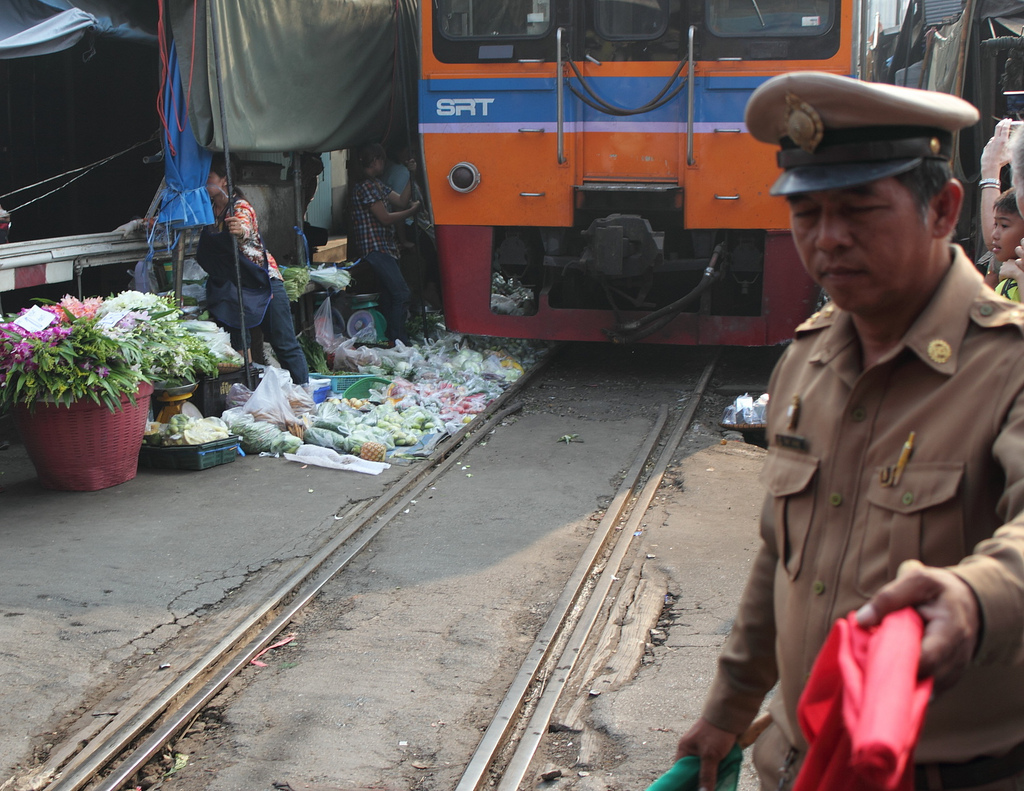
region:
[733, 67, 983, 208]
the man wears a tan hat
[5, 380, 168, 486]
the red pot holding the plant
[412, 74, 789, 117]
the blue stripe on the train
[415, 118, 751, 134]
the white stripe on the train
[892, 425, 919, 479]
the pen in the mans shirt is gold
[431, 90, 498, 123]
the letters "SRT" on the train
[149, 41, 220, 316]
the tied up blue umbrella next to the tracks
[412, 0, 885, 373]
a train stopped on the tracks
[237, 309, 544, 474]
a woman selling fruit near train tracks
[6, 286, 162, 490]
a red flower basket with flowers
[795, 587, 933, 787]
a red flag in a man's hand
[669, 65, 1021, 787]
a man in a tan officials uniform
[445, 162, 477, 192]
a light on a train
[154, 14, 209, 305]
a closed blue parasol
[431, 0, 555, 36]
a window on the front of a train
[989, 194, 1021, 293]
a child standing near train tracks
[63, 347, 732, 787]
metal train tracks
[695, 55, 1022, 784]
man wearing brown uniform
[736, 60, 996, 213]
brown hat the man is wearing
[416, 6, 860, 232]
orange and blue train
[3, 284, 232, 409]
purple white and pink flowers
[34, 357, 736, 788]
tracks the train is on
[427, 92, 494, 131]
white lettering on the train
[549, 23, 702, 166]
metal bars on the train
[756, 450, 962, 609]
pockets on the uniform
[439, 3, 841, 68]
windows on the train